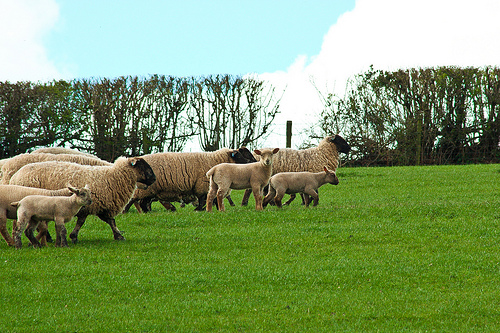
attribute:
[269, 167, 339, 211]
sheep — walking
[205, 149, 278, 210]
sheep — walking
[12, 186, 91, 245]
sheep — walking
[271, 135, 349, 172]
sheep — walking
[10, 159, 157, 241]
sheep — walking